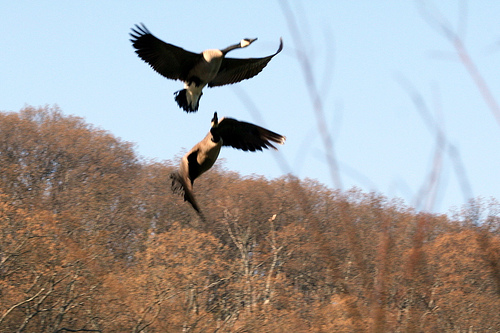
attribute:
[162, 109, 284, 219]
goose —  flapping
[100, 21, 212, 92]
wing — one, Canada, goose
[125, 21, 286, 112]
top goose — chasing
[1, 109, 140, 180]
leaves — brown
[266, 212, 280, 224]
bird — light, sitting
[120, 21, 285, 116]
bird — sitting, light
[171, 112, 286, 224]
bird — sitting, light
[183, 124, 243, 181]
bird's body — white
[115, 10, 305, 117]
goose — canadian, flying 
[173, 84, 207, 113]
feathers —  black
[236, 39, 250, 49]
cheek — white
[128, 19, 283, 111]
bird — black, white,  flying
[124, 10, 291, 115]
goose — canadian, flying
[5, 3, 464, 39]
sky — blue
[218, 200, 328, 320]
tree — autumnal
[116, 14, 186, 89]
wing — spread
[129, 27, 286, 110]
geese —  flying 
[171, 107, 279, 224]
geese —  flying 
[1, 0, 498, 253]
blue sky — pale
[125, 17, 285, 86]
wings — outstretched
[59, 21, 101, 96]
clouds — white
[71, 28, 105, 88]
clouds — white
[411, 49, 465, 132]
clouds — white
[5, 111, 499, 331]
leaves — brown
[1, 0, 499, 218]
sky — blue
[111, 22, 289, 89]
wings — spread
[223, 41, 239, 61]
neck — long